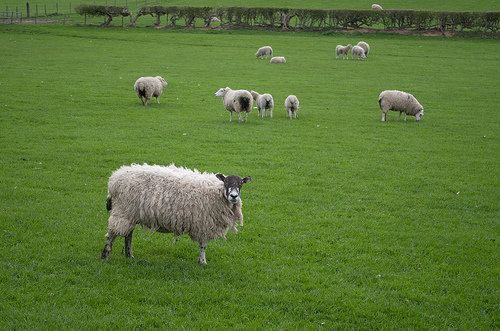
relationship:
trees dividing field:
[73, 1, 498, 46] [29, 26, 228, 77]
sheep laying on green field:
[271, 55, 286, 67] [1, 1, 498, 330]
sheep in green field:
[282, 94, 302, 120] [1, 1, 498, 330]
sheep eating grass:
[368, 71, 454, 129] [9, 118, 491, 162]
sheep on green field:
[376, 88, 425, 123] [1, 1, 498, 330]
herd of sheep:
[79, 21, 446, 271] [98, 40, 425, 266]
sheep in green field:
[45, 141, 342, 293] [1, 1, 498, 330]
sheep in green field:
[376, 88, 425, 123] [1, 1, 498, 330]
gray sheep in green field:
[132, 75, 167, 108] [1, 1, 498, 330]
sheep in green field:
[214, 85, 253, 125] [1, 1, 498, 330]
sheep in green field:
[242, 29, 279, 74] [1, 1, 498, 330]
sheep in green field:
[267, 55, 286, 67] [1, 1, 498, 330]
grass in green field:
[336, 169, 483, 307] [1, 1, 498, 330]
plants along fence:
[83, 5, 142, 31] [0, 3, 495, 33]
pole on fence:
[24, 0, 30, 17] [0, 0, 149, 25]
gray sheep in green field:
[132, 72, 171, 104] [1, 1, 498, 328]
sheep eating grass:
[282, 94, 302, 120] [280, 122, 343, 166]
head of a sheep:
[209, 163, 252, 210] [97, 155, 253, 267]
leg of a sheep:
[101, 217, 123, 261] [134, 166, 253, 250]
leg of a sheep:
[119, 225, 138, 264] [134, 166, 253, 250]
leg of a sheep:
[101, 217, 123, 256] [87, 152, 254, 282]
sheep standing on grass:
[285, 92, 301, 116] [1, 3, 499, 325]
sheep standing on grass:
[250, 89, 275, 119] [1, 3, 499, 325]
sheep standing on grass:
[213, 81, 253, 119] [1, 3, 499, 325]